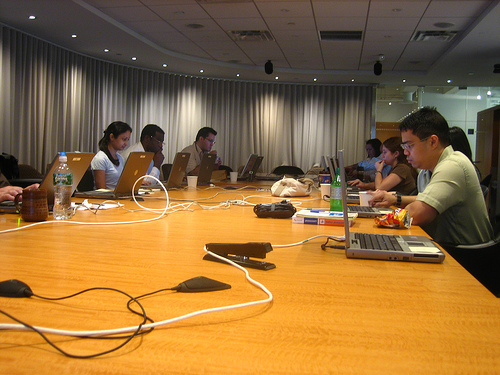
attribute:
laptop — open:
[332, 153, 461, 310]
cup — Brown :
[12, 187, 55, 222]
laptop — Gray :
[335, 143, 450, 265]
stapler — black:
[209, 229, 333, 290]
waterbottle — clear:
[50, 151, 77, 219]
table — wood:
[31, 145, 488, 372]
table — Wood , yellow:
[1, 175, 498, 371]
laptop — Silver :
[324, 142, 449, 266]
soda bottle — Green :
[327, 164, 344, 211]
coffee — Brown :
[176, 172, 205, 193]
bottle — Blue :
[51, 148, 95, 228]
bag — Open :
[368, 197, 415, 228]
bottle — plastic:
[38, 139, 83, 226]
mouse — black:
[0, 277, 35, 299]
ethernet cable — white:
[0, 229, 347, 336]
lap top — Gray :
[232, 150, 256, 192]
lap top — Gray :
[335, 145, 447, 263]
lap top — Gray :
[95, 151, 150, 202]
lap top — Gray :
[3, 146, 97, 210]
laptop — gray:
[331, 167, 458, 271]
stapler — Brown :
[197, 242, 262, 267]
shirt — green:
[415, 146, 492, 246]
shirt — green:
[415, 142, 491, 256]